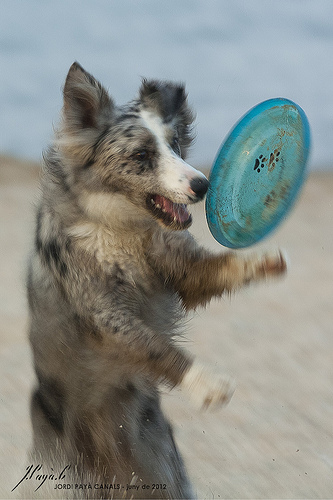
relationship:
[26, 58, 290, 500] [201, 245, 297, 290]
dog has paw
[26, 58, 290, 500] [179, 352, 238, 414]
dog has paw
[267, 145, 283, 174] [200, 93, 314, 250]
paw on frisbee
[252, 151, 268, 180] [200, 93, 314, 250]
paw on frisbee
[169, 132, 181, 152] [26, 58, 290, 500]
eye on dog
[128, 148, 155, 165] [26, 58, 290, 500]
eye on dog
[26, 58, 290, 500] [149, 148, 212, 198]
dog has nose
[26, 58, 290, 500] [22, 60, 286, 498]
dog has fur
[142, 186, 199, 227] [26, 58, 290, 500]
mouth of a dog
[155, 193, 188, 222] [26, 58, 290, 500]
tongue of a dog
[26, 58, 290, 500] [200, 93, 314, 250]
dog jumping for frisbee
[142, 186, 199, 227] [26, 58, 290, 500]
mouth of dog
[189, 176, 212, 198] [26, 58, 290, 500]
nose of dog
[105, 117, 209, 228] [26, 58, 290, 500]
face of dog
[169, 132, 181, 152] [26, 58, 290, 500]
eye of dog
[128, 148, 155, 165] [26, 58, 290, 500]
eye of dog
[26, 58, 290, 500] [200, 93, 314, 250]
dog biting frisbee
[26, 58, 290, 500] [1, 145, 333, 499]
dog on beach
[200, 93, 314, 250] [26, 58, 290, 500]
frisbee caught by dog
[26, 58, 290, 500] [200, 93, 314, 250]
dog playing frisbee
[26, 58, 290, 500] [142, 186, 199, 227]
dog has mouth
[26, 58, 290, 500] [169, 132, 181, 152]
dog has eye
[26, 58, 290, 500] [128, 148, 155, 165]
dog has eye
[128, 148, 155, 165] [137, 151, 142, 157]
eye has pupil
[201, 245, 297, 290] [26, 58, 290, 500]
paw on dog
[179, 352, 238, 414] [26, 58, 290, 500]
paw on dog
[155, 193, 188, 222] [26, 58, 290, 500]
tongue of dog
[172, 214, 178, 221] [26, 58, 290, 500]
tooth of dog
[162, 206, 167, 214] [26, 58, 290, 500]
tooth of dog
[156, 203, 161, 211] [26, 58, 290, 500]
tooth of dog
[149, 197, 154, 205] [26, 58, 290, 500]
tooth of dog